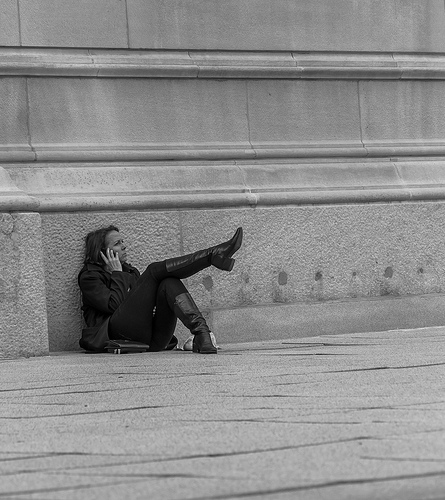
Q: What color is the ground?
A: Gray.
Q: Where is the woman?
A: On the ground.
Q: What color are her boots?
A: Black.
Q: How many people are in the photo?
A: One.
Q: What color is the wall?
A: Light gray.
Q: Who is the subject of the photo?
A: The man.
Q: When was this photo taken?
A: During the day.